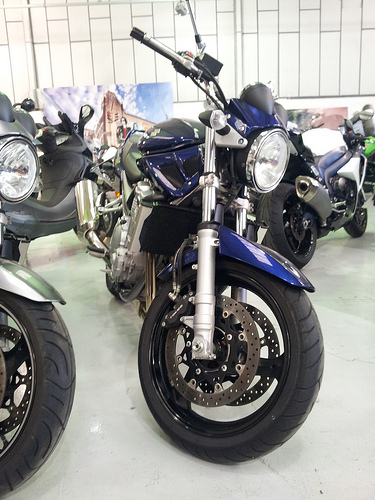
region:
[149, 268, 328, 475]
Front tire on a motorcycle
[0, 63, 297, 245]
Two motor bike headlights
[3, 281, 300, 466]
Two motorcycle front tires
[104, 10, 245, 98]
Motorcycle handle bar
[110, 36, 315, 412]
Shiny blue motor cycle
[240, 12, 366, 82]
Patterned window bars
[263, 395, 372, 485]
Motor cycle front tire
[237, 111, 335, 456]
Front end of blue motorcycle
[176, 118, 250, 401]
Chrome motorcycle parts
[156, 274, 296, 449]
Tire and spokes on motorcycle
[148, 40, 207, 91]
part of a gear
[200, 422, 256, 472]
part of a wheel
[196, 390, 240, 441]
edge of a rim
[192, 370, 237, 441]
part of a rim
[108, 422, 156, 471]
part of the floor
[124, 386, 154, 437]
edge of a shadow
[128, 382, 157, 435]
part of a shadow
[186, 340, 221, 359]
part of a bolt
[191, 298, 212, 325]
part of a metal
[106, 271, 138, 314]
part of a n engine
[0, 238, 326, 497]
the tires are black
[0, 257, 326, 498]
the tires look new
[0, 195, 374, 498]
the floor is dirty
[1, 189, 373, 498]
the floor is white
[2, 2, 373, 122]
the windows are behind the bikes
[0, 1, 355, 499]
the bikes are parked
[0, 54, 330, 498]
the bikes are side by side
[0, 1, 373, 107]
the windows are tall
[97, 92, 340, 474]
the bike is blue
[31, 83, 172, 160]
the painting is behind the bikes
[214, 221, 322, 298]
royal blue fender on tire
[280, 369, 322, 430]
rubber tire on bike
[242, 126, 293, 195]
headlight on front of bike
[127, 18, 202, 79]
handle bar with brake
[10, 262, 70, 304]
light reflection on fender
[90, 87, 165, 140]
illustration of people and building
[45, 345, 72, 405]
treads in rubber tire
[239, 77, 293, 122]
back of bike gages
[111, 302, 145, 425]
shadow of bike on floor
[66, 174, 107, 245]
chrome exhaust pipe on bike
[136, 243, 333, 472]
Black tire on a motorcycle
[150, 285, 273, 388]
Silver on a motorcycle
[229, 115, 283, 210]
Light on a motorcycle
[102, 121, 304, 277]
Blue motorcycle on gray pavement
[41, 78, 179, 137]
Picture in a garage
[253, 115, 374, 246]
Black and white motorcycle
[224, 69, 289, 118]
Dial on a motorcycle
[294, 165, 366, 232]
Silver muffler on a motorcycle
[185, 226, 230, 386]
Silver shock on a motorcycle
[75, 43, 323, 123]
White wall in a garage